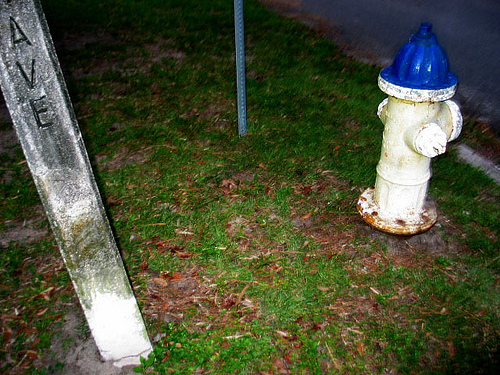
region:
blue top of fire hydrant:
[379, 17, 473, 89]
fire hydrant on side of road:
[359, 22, 466, 232]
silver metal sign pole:
[234, 0, 247, 133]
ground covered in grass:
[271, 84, 348, 165]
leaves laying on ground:
[155, 270, 210, 320]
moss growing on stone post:
[55, 216, 139, 303]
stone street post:
[0, 1, 155, 367]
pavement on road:
[343, 1, 476, 23]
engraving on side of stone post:
[3, 15, 62, 147]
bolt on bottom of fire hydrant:
[389, 213, 411, 229]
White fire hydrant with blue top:
[373, 22, 463, 232]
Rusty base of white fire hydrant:
[354, 185, 439, 237]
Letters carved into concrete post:
[5, 12, 58, 135]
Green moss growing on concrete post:
[48, 206, 126, 303]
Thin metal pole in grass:
[232, 7, 254, 145]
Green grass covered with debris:
[218, 215, 313, 308]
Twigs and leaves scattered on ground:
[151, 261, 243, 336]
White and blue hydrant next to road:
[343, 2, 498, 241]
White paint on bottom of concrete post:
[62, 280, 162, 371]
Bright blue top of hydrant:
[371, 7, 466, 100]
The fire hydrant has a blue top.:
[352, 19, 464, 272]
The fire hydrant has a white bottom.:
[352, 14, 464, 244]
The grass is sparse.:
[141, 133, 368, 372]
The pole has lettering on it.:
[0, 7, 68, 169]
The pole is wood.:
[7, 1, 187, 358]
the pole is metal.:
[216, 1, 257, 144]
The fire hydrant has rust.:
[343, 167, 445, 250]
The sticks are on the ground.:
[168, 134, 378, 355]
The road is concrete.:
[320, 3, 400, 55]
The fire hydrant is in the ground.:
[348, 19, 474, 262]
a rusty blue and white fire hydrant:
[355, 24, 465, 233]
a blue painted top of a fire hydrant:
[379, 27, 453, 89]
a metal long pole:
[231, 3, 251, 132]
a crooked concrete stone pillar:
[2, 1, 154, 359]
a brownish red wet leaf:
[175, 246, 187, 256]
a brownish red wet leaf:
[150, 233, 161, 243]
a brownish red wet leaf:
[295, 313, 303, 323]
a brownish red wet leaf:
[352, 341, 369, 353]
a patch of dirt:
[55, 309, 122, 373]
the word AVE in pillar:
[10, 13, 55, 130]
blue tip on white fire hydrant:
[353, 17, 468, 244]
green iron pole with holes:
[228, 5, 254, 138]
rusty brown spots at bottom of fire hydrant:
[354, 175, 441, 236]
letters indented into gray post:
[0, 3, 152, 363]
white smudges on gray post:
[18, 135, 165, 372]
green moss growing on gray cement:
[53, 206, 118, 277]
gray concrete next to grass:
[278, 0, 499, 122]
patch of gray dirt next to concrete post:
[50, 308, 136, 370]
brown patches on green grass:
[136, 174, 463, 368]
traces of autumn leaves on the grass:
[10, 166, 455, 371]